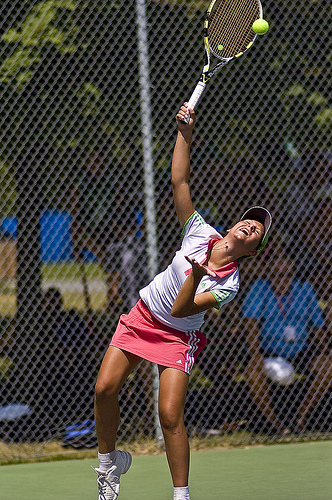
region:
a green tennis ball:
[249, 17, 271, 34]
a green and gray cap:
[238, 202, 273, 258]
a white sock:
[95, 453, 116, 466]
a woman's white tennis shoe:
[94, 447, 135, 499]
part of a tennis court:
[186, 439, 330, 498]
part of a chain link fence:
[0, 0, 328, 221]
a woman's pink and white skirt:
[105, 302, 200, 373]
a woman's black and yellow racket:
[178, 0, 264, 125]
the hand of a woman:
[182, 249, 220, 281]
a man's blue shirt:
[239, 280, 327, 353]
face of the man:
[202, 183, 303, 269]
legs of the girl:
[63, 363, 251, 456]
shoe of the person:
[87, 441, 125, 499]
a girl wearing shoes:
[65, 449, 143, 499]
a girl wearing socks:
[79, 431, 118, 465]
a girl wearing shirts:
[92, 297, 264, 390]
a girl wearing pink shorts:
[101, 306, 215, 399]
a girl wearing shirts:
[137, 233, 256, 337]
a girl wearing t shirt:
[135, 204, 246, 387]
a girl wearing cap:
[235, 184, 279, 271]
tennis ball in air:
[251, 15, 269, 35]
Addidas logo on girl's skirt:
[176, 359, 181, 362]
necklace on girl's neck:
[214, 237, 230, 264]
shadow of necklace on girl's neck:
[212, 243, 230, 264]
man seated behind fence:
[241, 252, 330, 434]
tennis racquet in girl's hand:
[177, 0, 262, 125]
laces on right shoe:
[90, 462, 107, 498]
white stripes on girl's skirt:
[184, 326, 200, 374]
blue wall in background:
[3, 207, 147, 262]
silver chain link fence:
[0, 0, 330, 448]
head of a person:
[212, 197, 280, 268]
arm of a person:
[148, 147, 212, 210]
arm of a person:
[167, 284, 212, 308]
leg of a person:
[34, 348, 146, 458]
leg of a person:
[139, 399, 197, 470]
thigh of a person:
[85, 346, 142, 384]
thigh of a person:
[135, 344, 195, 400]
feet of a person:
[87, 432, 140, 496]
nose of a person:
[247, 225, 257, 232]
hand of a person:
[185, 248, 217, 283]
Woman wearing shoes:
[92, 448, 132, 498]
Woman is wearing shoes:
[93, 447, 131, 498]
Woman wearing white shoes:
[92, 448, 134, 497]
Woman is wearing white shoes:
[92, 445, 137, 498]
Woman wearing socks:
[92, 446, 123, 467]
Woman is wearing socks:
[94, 445, 122, 468]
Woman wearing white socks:
[95, 445, 117, 472]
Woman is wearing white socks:
[94, 445, 120, 470]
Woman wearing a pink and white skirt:
[109, 292, 212, 375]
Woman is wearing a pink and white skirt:
[103, 295, 209, 377]